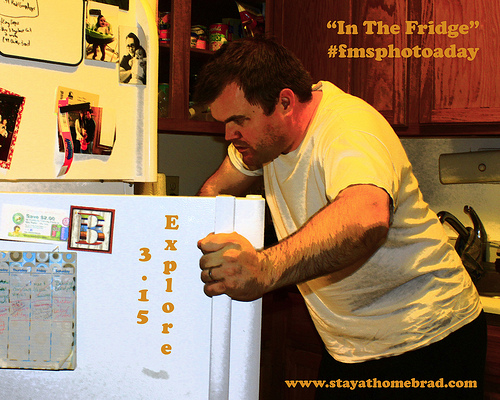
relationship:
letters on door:
[157, 208, 186, 360] [3, 188, 264, 397]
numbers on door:
[132, 242, 156, 339] [3, 188, 264, 397]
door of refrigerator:
[3, 188, 264, 397] [4, 3, 273, 399]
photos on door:
[49, 72, 125, 158] [3, 3, 169, 188]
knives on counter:
[435, 199, 491, 271] [438, 230, 499, 311]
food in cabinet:
[191, 5, 270, 44] [158, 0, 270, 140]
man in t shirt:
[195, 32, 490, 397] [215, 81, 483, 347]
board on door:
[0, 2, 98, 69] [3, 3, 169, 188]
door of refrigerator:
[3, 3, 169, 188] [0, 1, 162, 181]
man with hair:
[195, 32, 490, 397] [193, 36, 319, 109]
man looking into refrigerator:
[195, 32, 490, 397] [4, 3, 273, 399]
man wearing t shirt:
[195, 32, 490, 397] [215, 81, 483, 347]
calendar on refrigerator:
[3, 243, 82, 379] [4, 3, 273, 399]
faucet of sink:
[437, 203, 472, 242] [469, 266, 499, 288]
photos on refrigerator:
[49, 72, 125, 158] [4, 3, 273, 399]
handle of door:
[194, 197, 248, 400] [3, 188, 264, 397]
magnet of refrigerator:
[59, 203, 116, 253] [4, 3, 273, 399]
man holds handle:
[195, 32, 490, 397] [194, 197, 248, 400]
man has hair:
[195, 32, 490, 397] [193, 36, 319, 109]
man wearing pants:
[195, 32, 490, 397] [305, 314, 488, 394]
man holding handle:
[195, 32, 490, 397] [194, 197, 248, 400]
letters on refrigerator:
[157, 208, 186, 360] [4, 3, 273, 399]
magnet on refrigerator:
[59, 203, 116, 253] [4, 3, 273, 399]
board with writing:
[0, 2, 98, 69] [0, 1, 41, 47]